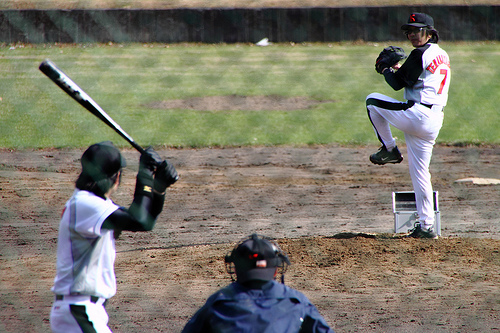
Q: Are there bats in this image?
A: Yes, there is a bat.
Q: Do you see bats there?
A: Yes, there is a bat.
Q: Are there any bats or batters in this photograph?
A: Yes, there is a bat.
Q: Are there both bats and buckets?
A: No, there is a bat but no buckets.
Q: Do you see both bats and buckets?
A: No, there is a bat but no buckets.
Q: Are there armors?
A: No, there are no armors.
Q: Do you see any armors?
A: No, there are no armors.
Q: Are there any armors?
A: No, there are no armors.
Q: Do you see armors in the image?
A: No, there are no armors.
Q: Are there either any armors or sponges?
A: No, there are no armors or sponges.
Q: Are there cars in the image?
A: No, there are no cars.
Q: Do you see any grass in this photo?
A: Yes, there is grass.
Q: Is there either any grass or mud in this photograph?
A: Yes, there is grass.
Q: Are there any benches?
A: No, there are no benches.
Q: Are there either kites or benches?
A: No, there are no benches or kites.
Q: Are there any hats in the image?
A: Yes, there is a hat.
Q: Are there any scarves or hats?
A: Yes, there is a hat.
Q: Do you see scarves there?
A: No, there are no scarves.